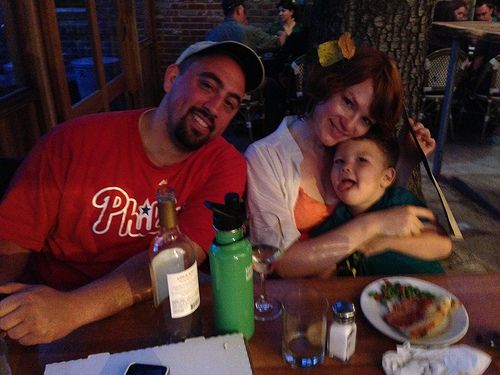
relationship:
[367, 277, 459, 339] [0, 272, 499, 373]
food on table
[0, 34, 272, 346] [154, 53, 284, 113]
man wears hat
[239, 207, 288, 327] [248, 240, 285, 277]
glass with wine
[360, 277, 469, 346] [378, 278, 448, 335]
plate with food